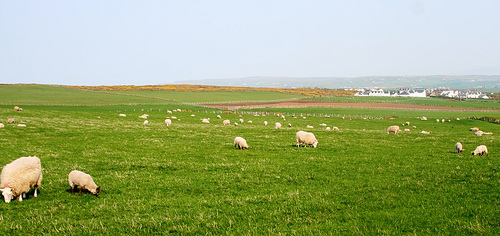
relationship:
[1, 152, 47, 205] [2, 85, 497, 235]
sheep in pasture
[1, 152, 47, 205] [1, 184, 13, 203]
sheep has face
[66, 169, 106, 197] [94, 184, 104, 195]
sheep has face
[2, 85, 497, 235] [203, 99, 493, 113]
pasture has dirt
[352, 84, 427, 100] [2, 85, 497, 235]
buildings by pasture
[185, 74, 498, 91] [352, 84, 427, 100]
mountain behind buildings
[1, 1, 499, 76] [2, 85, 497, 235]
sky over pasture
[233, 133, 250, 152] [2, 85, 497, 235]
sheep in pasture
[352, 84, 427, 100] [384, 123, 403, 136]
buildings beyond sheep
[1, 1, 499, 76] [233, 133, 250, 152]
sky above sheep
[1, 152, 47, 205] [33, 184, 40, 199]
sheep has leg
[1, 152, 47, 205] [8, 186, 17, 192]
sheep has ear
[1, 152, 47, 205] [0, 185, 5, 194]
sheep has ear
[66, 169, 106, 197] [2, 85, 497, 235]
sheep eating pasture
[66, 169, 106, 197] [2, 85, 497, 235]
sheep in pasture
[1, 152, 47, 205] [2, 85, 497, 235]
sheep eating pasture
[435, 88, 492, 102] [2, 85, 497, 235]
houses in front of pasture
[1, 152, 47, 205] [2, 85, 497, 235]
sheep eats pasture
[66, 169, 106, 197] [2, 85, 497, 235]
sheep eats pasture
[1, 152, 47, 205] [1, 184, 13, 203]
sheep has head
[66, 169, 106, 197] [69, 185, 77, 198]
sheep has leg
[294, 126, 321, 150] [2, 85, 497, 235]
sheep in pasture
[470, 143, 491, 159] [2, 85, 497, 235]
sheep in pasture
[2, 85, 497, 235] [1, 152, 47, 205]
pasture filled with sheep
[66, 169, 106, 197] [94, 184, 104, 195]
sheep has head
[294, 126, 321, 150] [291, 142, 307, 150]
sheep has shadow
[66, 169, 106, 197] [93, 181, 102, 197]
sheep has head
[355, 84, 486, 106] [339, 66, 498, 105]
dwellings in town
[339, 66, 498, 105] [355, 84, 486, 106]
town with dwellings